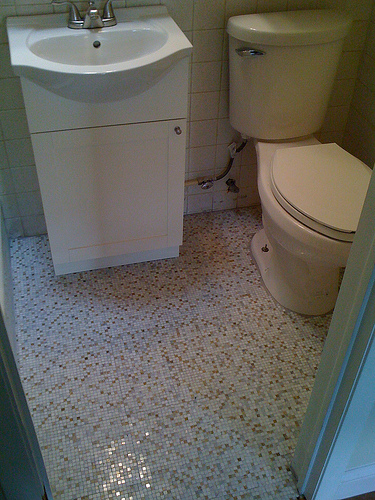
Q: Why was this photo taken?
A: For a magazine.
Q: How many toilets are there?
A: One.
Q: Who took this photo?
A: The landlord.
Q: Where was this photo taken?
A: The bathroom.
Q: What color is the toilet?
A: White.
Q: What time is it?
A: Noon.